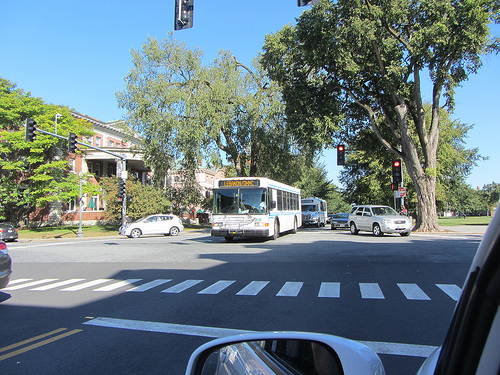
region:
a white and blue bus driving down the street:
[210, 176, 300, 240]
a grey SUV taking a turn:
[349, 202, 411, 237]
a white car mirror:
[185, 329, 386, 374]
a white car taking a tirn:
[119, 212, 179, 238]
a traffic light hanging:
[332, 140, 346, 167]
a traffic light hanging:
[390, 156, 400, 180]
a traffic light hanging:
[172, 3, 191, 27]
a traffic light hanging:
[24, 116, 35, 138]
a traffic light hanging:
[65, 131, 79, 151]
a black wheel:
[131, 226, 143, 238]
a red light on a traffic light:
[328, 130, 355, 180]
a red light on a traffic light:
[384, 138, 419, 187]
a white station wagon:
[136, 205, 183, 263]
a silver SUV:
[343, 198, 426, 236]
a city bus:
[202, 164, 314, 254]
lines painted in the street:
[87, 268, 460, 309]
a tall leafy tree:
[277, 22, 477, 222]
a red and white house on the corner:
[0, 106, 155, 259]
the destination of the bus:
[213, 171, 263, 190]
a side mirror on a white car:
[169, 313, 421, 373]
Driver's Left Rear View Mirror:
[175, 326, 386, 372]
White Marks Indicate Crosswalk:
[0, 265, 485, 305]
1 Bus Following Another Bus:
[191, 165, 326, 245]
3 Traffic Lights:
[15, 110, 130, 245]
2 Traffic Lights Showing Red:
[320, 135, 430, 240]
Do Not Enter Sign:
[390, 180, 410, 195]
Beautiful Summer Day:
[5, 5, 495, 370]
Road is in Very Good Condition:
[0, 216, 491, 371]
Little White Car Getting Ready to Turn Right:
[110, 206, 186, 241]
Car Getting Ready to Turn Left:
[343, 198, 419, 240]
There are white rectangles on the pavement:
[129, 265, 415, 312]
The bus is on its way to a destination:
[209, 152, 319, 252]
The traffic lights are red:
[329, 137, 406, 197]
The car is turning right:
[112, 187, 210, 252]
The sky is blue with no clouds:
[18, 40, 111, 112]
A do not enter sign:
[397, 187, 412, 206]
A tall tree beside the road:
[302, 41, 496, 256]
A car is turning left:
[349, 190, 434, 253]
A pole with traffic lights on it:
[7, 93, 138, 228]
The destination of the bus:
[218, 179, 273, 192]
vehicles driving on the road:
[60, 91, 471, 298]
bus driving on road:
[208, 161, 312, 241]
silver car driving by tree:
[365, 204, 419, 242]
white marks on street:
[57, 257, 392, 334]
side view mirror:
[204, 305, 404, 367]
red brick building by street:
[14, 120, 128, 260]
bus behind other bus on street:
[304, 178, 335, 239]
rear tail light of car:
[0, 231, 72, 265]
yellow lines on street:
[27, 308, 84, 372]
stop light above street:
[167, 5, 211, 73]